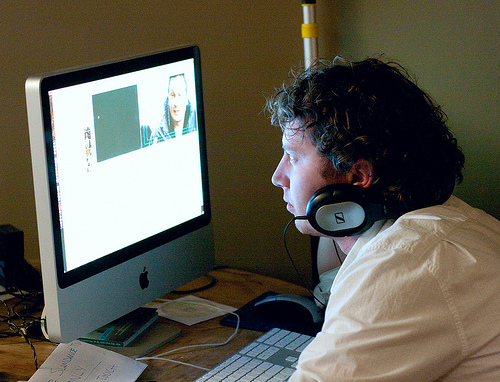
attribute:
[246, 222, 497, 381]
shirt — white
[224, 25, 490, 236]
hair — brown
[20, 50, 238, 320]
monitor — on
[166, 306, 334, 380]
keyboard — white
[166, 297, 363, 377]
keyboard — white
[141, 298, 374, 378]
keyboard — white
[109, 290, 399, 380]
keyboard — white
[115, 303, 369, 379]
keyboard — white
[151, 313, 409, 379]
keyboard — white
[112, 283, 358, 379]
keyboard — white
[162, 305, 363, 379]
keyboard — white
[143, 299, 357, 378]
computer keyboard — white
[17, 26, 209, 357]
monitor — apple brand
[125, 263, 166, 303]
logo — apple brand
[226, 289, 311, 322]
pad — mouse 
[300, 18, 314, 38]
plastic —  yellow piece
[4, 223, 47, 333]
container —  plastic disc 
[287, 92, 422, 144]
hair —  curly 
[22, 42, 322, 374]
components — wires connecting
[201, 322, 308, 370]
keyboard — white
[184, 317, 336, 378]
keyboard — white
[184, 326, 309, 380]
keyboard — white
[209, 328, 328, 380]
keyboard — white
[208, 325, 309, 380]
keyboard — white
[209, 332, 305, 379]
keyboard — white